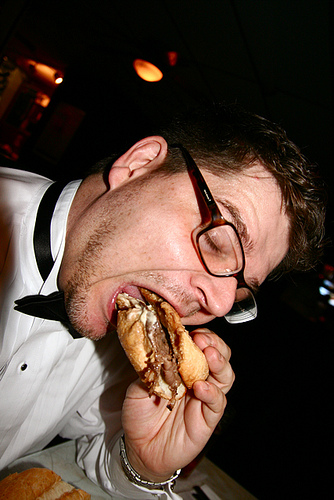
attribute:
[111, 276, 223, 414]
sandwich — toasted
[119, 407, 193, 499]
band — silver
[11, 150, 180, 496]
shirt — white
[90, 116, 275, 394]
man — eating, holding, leaning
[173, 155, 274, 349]
glasses — brown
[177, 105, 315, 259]
hair — brown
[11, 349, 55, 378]
button — black, blakc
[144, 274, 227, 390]
bread — crunchy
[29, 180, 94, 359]
bowtie — black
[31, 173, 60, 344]
band — black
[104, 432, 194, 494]
bracelet — silver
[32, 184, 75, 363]
tie — black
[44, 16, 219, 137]
lights — orange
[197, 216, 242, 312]
eyes — closed